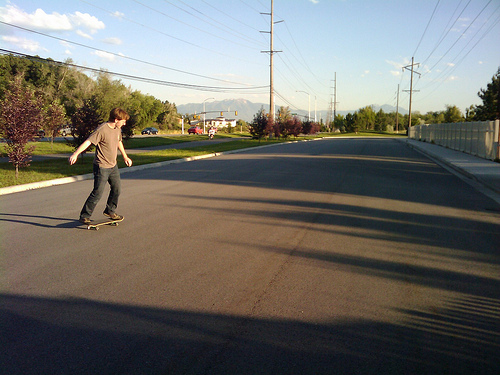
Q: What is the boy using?
A: A skateboard.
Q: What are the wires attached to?
A: The electric poles.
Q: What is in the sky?
A: Clouds.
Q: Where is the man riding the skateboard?
A: In the street.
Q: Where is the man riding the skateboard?
A: In the street.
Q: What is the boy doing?
A: Skateboarding.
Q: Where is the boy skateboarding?
A: In the road.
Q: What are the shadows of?
A: Trees.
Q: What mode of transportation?
A: Skateboard.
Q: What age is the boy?
A: Teenager.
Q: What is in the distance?
A: Mountains.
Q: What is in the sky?
A: Powerlines.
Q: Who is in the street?
A: The boy.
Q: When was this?
A: Daytime.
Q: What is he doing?
A: Skating.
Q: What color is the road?
A: Grey.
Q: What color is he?
A: White.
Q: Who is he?
A: A boy.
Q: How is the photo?
A: Clear.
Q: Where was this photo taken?
A: On the street.